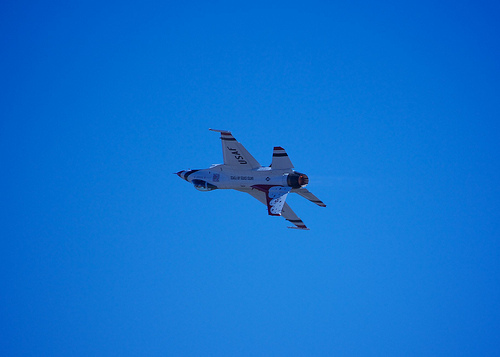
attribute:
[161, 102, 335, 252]
jet — flying, upside down, white, doing tricks, air force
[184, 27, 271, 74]
sky — blue, empty, clear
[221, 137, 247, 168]
logo — usaf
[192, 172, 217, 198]
cockpit — glass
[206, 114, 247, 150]
stripes — blue, black, red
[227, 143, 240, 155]
letters — black, blue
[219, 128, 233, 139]
tip — black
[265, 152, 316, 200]
rear — black